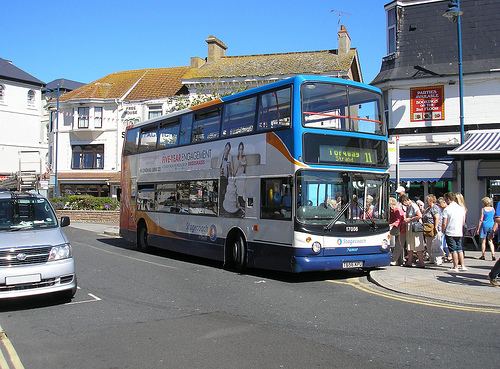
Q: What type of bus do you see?
A: Double decker.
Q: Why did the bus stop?
A: Picking up passengers.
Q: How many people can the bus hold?
A: No indication.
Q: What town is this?
A: No indication.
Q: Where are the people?
A: Sidewalk.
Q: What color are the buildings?
A: White.